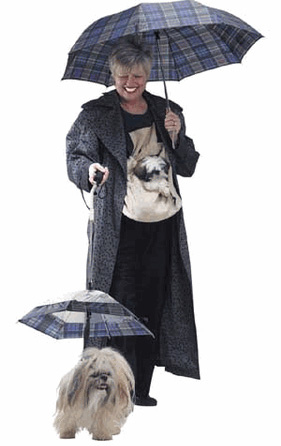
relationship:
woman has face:
[61, 44, 200, 413] [114, 68, 147, 101]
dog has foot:
[51, 343, 136, 445] [56, 430, 81, 442]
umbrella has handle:
[57, 2, 267, 134] [154, 36, 181, 141]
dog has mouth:
[51, 343, 136, 445] [90, 380, 110, 392]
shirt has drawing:
[116, 101, 185, 228] [122, 120, 186, 228]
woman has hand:
[61, 44, 200, 413] [84, 162, 116, 192]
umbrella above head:
[57, 2, 267, 134] [105, 37, 157, 103]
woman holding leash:
[61, 44, 200, 413] [82, 191, 99, 350]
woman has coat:
[61, 44, 200, 413] [62, 88, 202, 384]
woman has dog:
[61, 44, 200, 413] [51, 343, 136, 445]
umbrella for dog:
[9, 285, 160, 357] [51, 343, 136, 445]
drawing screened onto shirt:
[122, 120, 186, 228] [116, 101, 185, 228]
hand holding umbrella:
[161, 108, 182, 139] [57, 2, 267, 134]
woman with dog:
[61, 44, 200, 413] [51, 343, 136, 445]